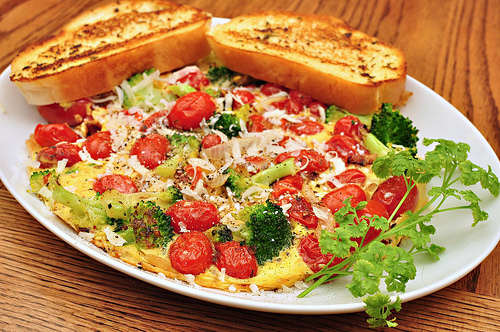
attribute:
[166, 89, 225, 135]
tomato — red, on frittata, small, sliced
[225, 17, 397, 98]
bread — pieced, toasted, sliced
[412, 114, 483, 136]
plate — white, covered with food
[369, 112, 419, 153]
broccoli — browned, on frittata, green, stemmed, in pieces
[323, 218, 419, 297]
parsley — green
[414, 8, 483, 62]
table — wooden, brown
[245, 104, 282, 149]
cheese — shredded, on frittata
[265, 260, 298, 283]
eggs — yellow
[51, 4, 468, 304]
food — red, green, delicious, vegetable frittata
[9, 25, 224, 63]
bread — pieced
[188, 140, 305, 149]
onion — on frittata